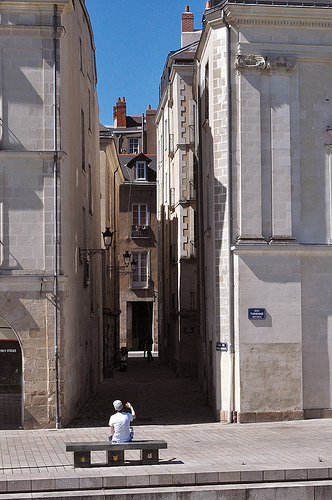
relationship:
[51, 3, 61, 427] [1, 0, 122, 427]
pipe going up building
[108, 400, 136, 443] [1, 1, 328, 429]
guy standing between buildings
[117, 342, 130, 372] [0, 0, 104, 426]
motorcycle against building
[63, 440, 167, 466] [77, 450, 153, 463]
bench with cut outs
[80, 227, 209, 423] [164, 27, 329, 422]
passage between building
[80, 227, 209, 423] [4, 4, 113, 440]
passage between building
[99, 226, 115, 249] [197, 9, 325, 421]
lantern on building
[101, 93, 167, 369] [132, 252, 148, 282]
building has window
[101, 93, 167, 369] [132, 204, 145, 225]
building has window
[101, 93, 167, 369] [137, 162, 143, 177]
building has window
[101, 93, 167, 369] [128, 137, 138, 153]
building has window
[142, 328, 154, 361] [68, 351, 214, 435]
person in alley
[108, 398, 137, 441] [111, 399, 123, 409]
guy wearing a hat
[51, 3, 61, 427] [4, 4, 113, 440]
pipe on building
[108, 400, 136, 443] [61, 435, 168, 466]
guy sitting on bench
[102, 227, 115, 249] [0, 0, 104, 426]
lantern on side of building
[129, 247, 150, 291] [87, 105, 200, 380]
balcony on building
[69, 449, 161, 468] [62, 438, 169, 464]
brandigs on bench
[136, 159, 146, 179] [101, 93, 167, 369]
window on building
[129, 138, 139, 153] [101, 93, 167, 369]
window on building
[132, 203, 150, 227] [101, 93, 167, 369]
window on building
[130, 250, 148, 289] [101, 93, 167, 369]
window on building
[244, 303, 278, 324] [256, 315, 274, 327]
poster with shadow